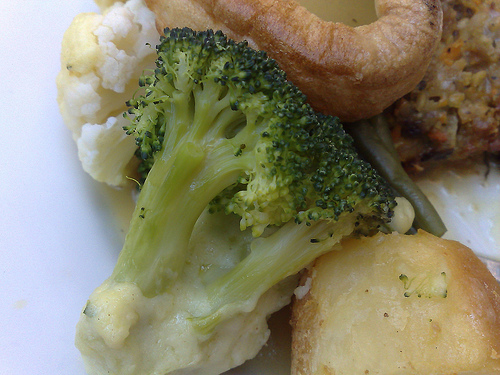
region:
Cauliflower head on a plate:
[41, 0, 162, 190]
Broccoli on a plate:
[83, 27, 394, 373]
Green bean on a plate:
[347, 115, 449, 243]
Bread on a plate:
[146, 0, 444, 132]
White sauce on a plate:
[408, 154, 498, 261]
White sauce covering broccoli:
[79, 222, 279, 373]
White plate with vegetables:
[2, 0, 132, 372]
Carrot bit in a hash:
[441, 40, 464, 61]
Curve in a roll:
[291, 0, 383, 29]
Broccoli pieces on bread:
[396, 270, 448, 298]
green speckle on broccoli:
[278, 160, 307, 187]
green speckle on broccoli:
[329, 199, 351, 218]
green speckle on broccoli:
[352, 181, 377, 196]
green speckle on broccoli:
[364, 176, 394, 208]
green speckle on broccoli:
[334, 139, 357, 164]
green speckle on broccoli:
[321, 174, 345, 207]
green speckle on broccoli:
[329, 136, 346, 163]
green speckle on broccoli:
[328, 121, 358, 143]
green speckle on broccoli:
[321, 127, 345, 147]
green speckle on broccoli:
[296, 124, 322, 146]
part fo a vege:
[351, 182, 376, 204]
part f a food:
[385, 255, 408, 310]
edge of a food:
[370, 228, 396, 285]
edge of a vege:
[292, 189, 334, 280]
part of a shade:
[269, 315, 295, 369]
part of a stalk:
[214, 241, 279, 303]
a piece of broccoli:
[80, 26, 395, 373]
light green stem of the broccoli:
[111, 138, 228, 274]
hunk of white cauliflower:
[41, 0, 183, 182]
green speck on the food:
[393, 265, 415, 302]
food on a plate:
[31, 0, 493, 372]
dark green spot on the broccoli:
[135, 204, 150, 220]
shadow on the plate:
[94, 189, 133, 249]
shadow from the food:
[98, 178, 138, 250]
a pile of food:
[42, 0, 498, 373]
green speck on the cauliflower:
[66, 61, 73, 70]